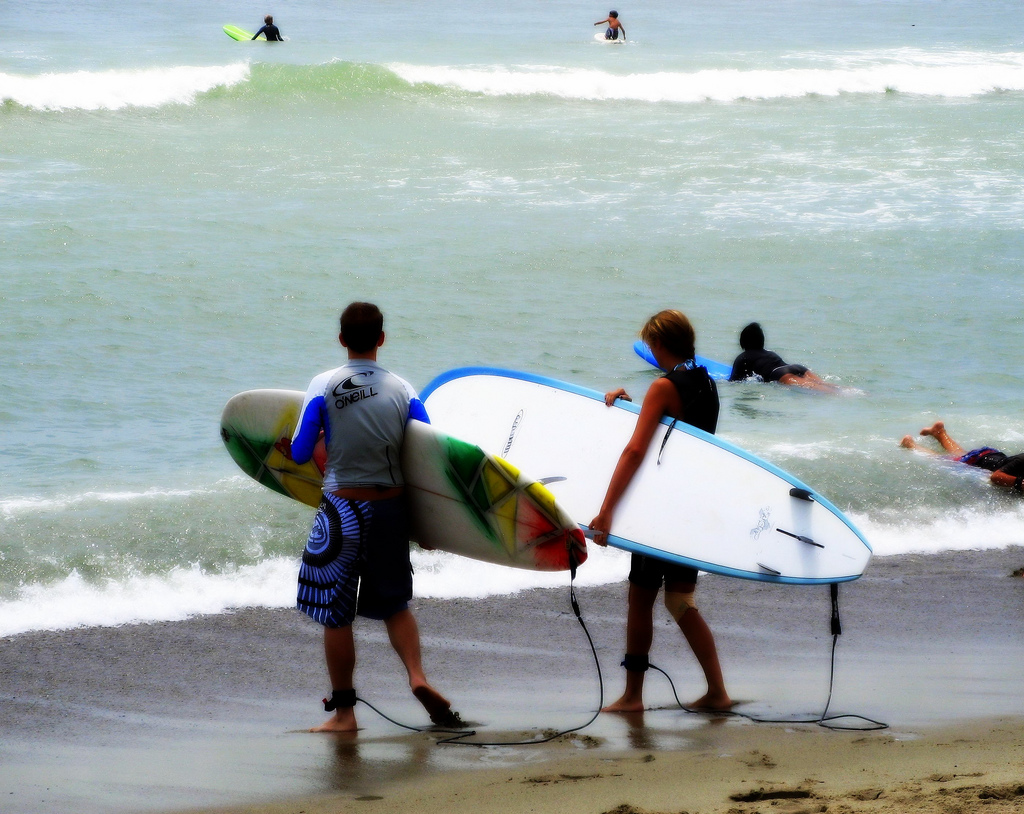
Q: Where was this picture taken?
A: At the beach.